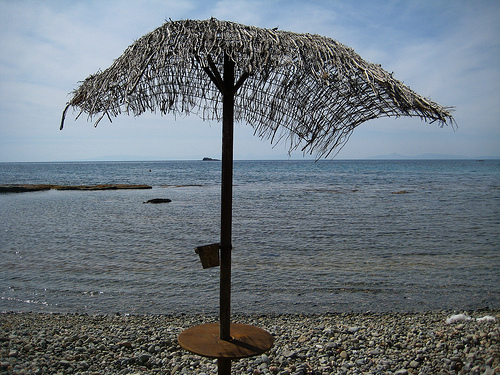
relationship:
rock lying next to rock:
[0, 317, 500, 375] [408, 360, 420, 370]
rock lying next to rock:
[0, 317, 500, 375] [128, 355, 135, 364]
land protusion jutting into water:
[0, 183, 152, 195] [302, 201, 457, 284]